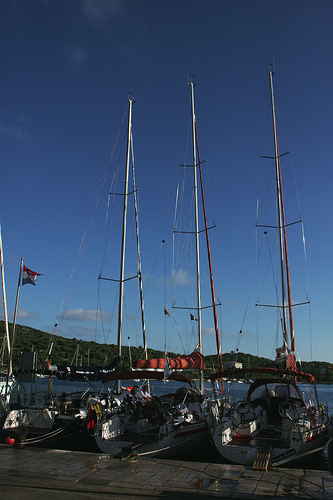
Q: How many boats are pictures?
A: Three.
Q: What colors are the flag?
A: Red, white, and blue.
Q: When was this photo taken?
A: During the day.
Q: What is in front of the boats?
A: Dock.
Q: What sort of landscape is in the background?
A: Hills.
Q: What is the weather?
A: Clear.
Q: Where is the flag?
A: Left of boats.